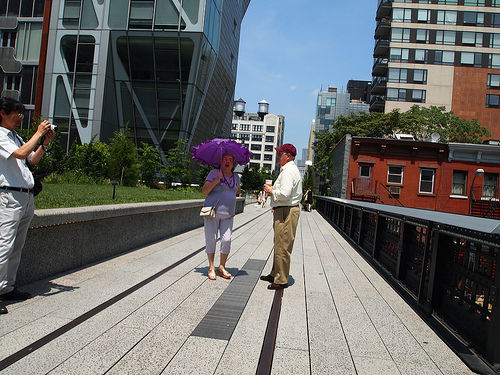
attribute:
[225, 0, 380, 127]
sky — cloudless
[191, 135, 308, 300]
couple — older  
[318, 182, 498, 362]
railing — black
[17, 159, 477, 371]
walkway — wood 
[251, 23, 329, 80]
sky — blue , clear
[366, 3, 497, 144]
building — tall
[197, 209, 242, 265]
pants — beige, capri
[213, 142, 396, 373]
sidewalk — long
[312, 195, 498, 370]
railing — black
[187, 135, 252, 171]
purple umbrella — purple  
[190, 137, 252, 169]
edges — ruffled  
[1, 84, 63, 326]
man — Asian  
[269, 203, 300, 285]
pants — White 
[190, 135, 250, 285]
people — standing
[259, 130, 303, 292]
people — standing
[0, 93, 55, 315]
people — standing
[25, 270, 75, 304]
shadow — the man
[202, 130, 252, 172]
umbrella — purple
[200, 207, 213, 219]
purse — white 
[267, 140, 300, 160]
hat — red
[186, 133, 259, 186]
parasol — purple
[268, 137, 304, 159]
hat — Burgundy 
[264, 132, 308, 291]
man —  is casting a shadow